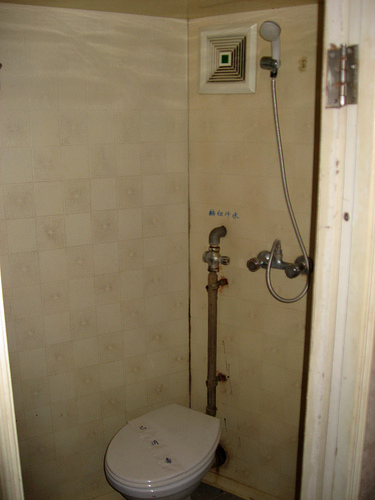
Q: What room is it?
A: It is a bathroom.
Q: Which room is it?
A: It is a bathroom.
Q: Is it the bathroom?
A: Yes, it is the bathroom.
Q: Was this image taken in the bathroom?
A: Yes, it was taken in the bathroom.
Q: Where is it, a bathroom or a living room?
A: It is a bathroom.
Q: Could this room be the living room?
A: No, it is the bathroom.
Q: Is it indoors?
A: Yes, it is indoors.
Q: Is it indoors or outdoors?
A: It is indoors.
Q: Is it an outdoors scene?
A: No, it is indoors.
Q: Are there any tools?
A: No, there are no tools.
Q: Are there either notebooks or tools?
A: No, there are no tools or notebooks.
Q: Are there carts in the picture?
A: No, there are no carts.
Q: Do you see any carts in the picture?
A: No, there are no carts.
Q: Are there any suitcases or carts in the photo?
A: No, there are no carts or suitcases.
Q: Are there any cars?
A: No, there are no cars.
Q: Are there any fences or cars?
A: No, there are no cars or fences.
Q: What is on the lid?
A: The sign is on the lid.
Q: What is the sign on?
A: The sign is on the lid.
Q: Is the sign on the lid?
A: Yes, the sign is on the lid.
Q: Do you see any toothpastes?
A: No, there are no toothpastes.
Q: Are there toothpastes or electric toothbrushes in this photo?
A: No, there are no toothpastes or electric toothbrushes.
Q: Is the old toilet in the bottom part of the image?
A: Yes, the toilet is in the bottom of the image.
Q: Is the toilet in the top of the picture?
A: No, the toilet is in the bottom of the image.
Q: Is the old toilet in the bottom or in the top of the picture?
A: The toilet is in the bottom of the image.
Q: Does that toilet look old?
A: Yes, the toilet is old.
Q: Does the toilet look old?
A: Yes, the toilet is old.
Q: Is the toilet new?
A: No, the toilet is old.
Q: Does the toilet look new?
A: No, the toilet is old.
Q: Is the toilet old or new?
A: The toilet is old.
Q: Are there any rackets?
A: No, there are no rackets.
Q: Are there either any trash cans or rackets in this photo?
A: No, there are no rackets or trash cans.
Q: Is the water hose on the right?
A: Yes, the water hose is on the right of the image.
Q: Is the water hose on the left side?
A: No, the water hose is on the right of the image.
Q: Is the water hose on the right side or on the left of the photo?
A: The water hose is on the right of the image.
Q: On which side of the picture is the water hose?
A: The water hose is on the right of the image.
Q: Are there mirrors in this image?
A: No, there are no mirrors.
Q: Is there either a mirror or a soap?
A: No, there are no mirrors or soaps.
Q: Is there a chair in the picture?
A: No, there are no chairs.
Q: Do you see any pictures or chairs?
A: No, there are no chairs or pictures.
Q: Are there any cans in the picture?
A: No, there are no cans.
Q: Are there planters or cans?
A: No, there are no cans or planters.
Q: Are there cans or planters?
A: No, there are no cans or planters.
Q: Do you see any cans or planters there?
A: No, there are no cans or planters.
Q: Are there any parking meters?
A: No, there are no parking meters.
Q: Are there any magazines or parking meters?
A: No, there are no parking meters or magazines.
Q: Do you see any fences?
A: No, there are no fences.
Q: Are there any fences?
A: No, there are no fences.